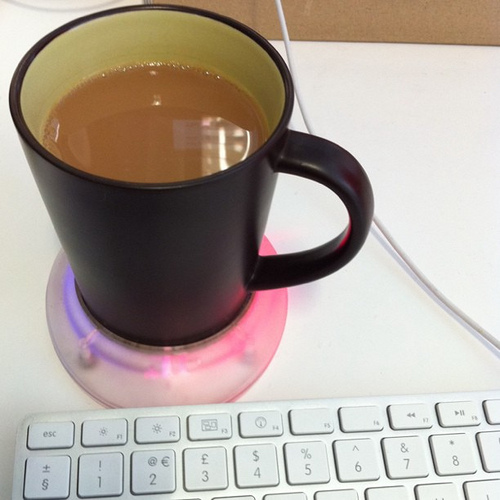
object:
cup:
[6, 3, 376, 348]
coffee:
[43, 61, 268, 182]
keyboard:
[11, 389, 499, 499]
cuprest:
[43, 232, 290, 409]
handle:
[252, 130, 374, 291]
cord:
[373, 213, 495, 350]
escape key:
[27, 421, 76, 453]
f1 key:
[80, 417, 129, 448]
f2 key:
[133, 416, 180, 443]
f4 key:
[237, 409, 284, 438]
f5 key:
[287, 406, 335, 436]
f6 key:
[337, 402, 385, 433]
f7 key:
[386, 402, 433, 430]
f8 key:
[433, 401, 483, 429]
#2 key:
[129, 449, 177, 495]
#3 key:
[182, 447, 229, 491]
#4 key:
[233, 443, 280, 489]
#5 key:
[282, 441, 330, 485]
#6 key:
[332, 438, 381, 484]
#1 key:
[75, 451, 123, 499]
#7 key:
[380, 433, 429, 480]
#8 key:
[427, 432, 476, 476]